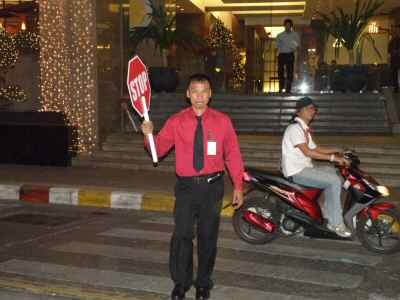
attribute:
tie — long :
[170, 115, 206, 166]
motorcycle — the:
[237, 160, 399, 242]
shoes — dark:
[168, 285, 209, 298]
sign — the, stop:
[97, 50, 170, 120]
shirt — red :
[172, 103, 270, 232]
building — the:
[214, 94, 392, 136]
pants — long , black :
[149, 166, 246, 298]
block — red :
[18, 184, 54, 208]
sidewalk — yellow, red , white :
[15, 157, 391, 248]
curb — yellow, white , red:
[2, 182, 399, 231]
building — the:
[34, 0, 396, 192]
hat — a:
[284, 95, 316, 109]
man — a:
[272, 15, 298, 95]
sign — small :
[101, 51, 171, 164]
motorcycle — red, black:
[232, 144, 396, 254]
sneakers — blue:
[325, 220, 353, 240]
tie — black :
[190, 111, 206, 172]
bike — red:
[233, 157, 398, 254]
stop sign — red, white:
[126, 55, 150, 116]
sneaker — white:
[326, 220, 352, 239]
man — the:
[270, 91, 363, 238]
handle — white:
[136, 94, 162, 166]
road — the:
[0, 196, 399, 298]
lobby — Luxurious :
[121, 10, 398, 92]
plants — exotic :
[134, 1, 383, 94]